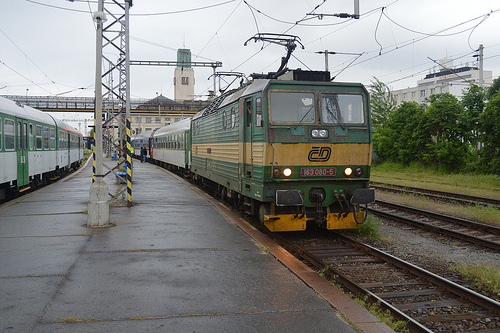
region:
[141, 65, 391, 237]
a train over the railroad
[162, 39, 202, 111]
a tower over a building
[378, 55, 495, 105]
a building on right side of tran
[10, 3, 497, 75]
wires above the train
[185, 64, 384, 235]
front car of train is color green and yellow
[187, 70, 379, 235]
car has a yellow stripe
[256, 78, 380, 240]
front of train is yellow and green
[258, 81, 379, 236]
yellow strip on front of train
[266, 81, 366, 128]
two wipes on windshield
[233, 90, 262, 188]
front door of train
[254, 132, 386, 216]
the headlights are on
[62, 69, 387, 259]
the train is stopped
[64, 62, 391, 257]
the train is picking up passengers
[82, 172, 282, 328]
the ground is wet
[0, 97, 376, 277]
2 trains are at the stop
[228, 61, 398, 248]
the train is green and yellow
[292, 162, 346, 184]
the license plate is red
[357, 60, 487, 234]
trees are to the right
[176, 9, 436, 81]
wires above the train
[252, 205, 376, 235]
the stoppers are yellow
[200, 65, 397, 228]
train on metal track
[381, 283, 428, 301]
railroad tie in track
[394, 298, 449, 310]
railroad tie in track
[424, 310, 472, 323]
railroad tie in track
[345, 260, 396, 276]
railroad tie in track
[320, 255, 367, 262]
railroad tie in track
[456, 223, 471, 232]
railroad tie in track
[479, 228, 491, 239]
railroad tie in track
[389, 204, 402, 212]
railroad tie in track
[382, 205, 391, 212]
railroad tie in track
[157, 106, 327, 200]
green and yellow train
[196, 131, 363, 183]
yellow stripe on train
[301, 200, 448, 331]
train tracks are brown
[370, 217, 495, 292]
grey gravel between tracks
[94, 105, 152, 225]
yellow and black poles on concrete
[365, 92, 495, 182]
green trees beside tracks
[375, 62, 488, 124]
white building behind trees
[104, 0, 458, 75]
black power lines over train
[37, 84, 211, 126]
bridge is over train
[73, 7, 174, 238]
grey pole left of train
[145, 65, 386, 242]
a train on a railroad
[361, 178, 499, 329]
three sets of railroad tracks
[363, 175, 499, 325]
railroads are covered with grass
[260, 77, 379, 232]
front of train is green and yellow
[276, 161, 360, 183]
headlights on front of train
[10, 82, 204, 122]
a bridge on the background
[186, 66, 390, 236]
car of train is green and yellow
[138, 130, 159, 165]
person in front of red door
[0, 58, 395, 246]
two trains on side of platform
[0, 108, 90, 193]
windows and doors of train are green